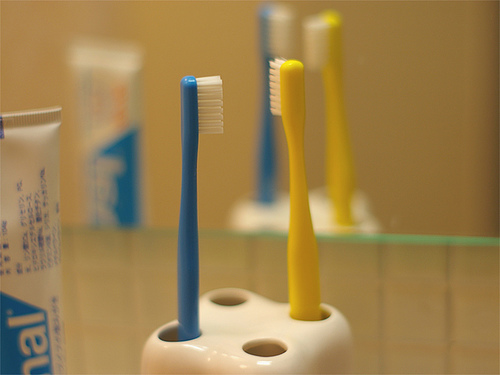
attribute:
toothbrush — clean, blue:
[177, 74, 224, 340]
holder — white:
[140, 286, 353, 374]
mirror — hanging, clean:
[1, 1, 500, 249]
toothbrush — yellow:
[268, 55, 323, 321]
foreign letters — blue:
[0, 166, 65, 372]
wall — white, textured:
[61, 232, 499, 374]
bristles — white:
[269, 57, 290, 116]